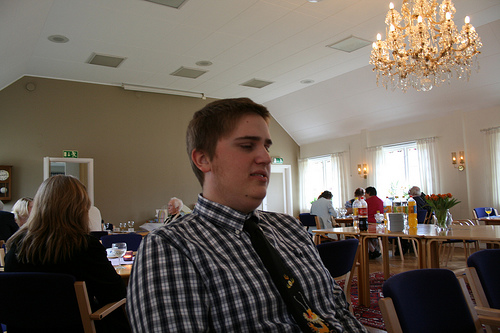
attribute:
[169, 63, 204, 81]
air vent — white, large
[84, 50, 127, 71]
air vent — large, white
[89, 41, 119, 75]
vent — AIR, WHITE, LARGE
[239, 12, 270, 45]
ceiling — AIR, WHITE, LARGE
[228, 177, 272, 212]
chin — DOUBLE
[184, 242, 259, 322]
shirt — DRESS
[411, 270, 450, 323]
chairs — BLUE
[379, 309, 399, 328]
arms — WOOD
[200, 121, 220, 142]
hair — BROWN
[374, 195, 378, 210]
shirt — RED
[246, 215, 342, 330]
tie — BLACK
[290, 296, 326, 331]
design — YELLOW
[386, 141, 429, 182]
curtains — WHITE